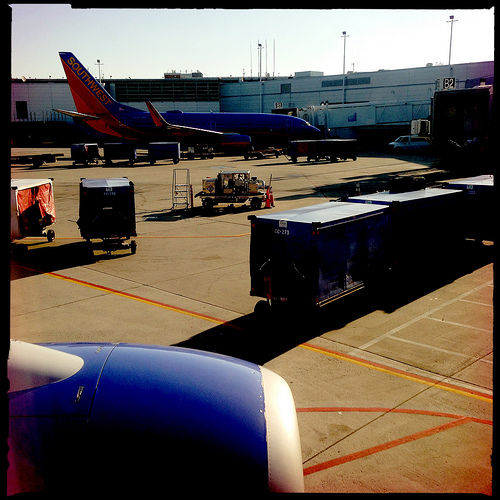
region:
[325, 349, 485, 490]
The ground is concrete.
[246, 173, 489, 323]
The car is carrying luggage.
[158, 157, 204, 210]
The stairs are white.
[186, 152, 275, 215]
The tractor is on the road.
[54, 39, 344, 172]
The plane is blue and red.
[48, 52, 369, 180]
The plane is by the airport.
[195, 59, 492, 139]
The airport is white.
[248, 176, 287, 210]
The person is working.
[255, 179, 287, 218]
They are wearing orange.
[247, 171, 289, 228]
They are standing.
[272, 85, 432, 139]
a white airport gate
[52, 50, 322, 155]
a blue and red airplane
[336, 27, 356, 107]
a gray light pole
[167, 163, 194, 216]
a silver ladder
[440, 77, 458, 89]
a small gate sign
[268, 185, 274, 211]
an orange cone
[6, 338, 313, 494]
the engine of a plane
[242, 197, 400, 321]
a baggage car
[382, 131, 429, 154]
a white cargo van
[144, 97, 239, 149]
the wing of an airplane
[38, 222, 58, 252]
this is a wheel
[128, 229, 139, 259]
a small black wheel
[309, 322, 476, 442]
a red painted line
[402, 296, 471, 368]
some white painted lines,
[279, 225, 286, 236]
the white number 2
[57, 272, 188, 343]
a yellow painted line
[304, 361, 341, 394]
the grey concrete ground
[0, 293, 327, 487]
the nose of a plane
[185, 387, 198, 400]
the color dark blue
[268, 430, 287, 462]
this is white paint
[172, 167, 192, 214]
short ladder on tarmac.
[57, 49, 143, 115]
Southwest airlines tail fin.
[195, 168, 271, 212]
Maintaince truck on tarmac.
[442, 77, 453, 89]
Black and white sign showing section 'B2'.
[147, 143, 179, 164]
truck section with wheels.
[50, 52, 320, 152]
Blue and red airplane at airport.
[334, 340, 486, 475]
Orange and yellow markings on tarmac.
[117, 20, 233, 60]
Hazy white sky.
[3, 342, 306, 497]
Blue and white engine.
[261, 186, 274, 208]
Orange cone on tarmac.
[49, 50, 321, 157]
a red and blue airplane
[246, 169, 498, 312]
blue baggage carriers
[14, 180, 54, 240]
orange tarp on back on white carrier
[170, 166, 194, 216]
a small silver ladder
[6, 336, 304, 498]
closeup of blue and white engine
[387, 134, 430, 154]
a white parked van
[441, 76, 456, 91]
black and white gate number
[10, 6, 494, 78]
clear light blue sky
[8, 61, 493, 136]
white airport building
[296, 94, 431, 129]
white walkway to enter plane